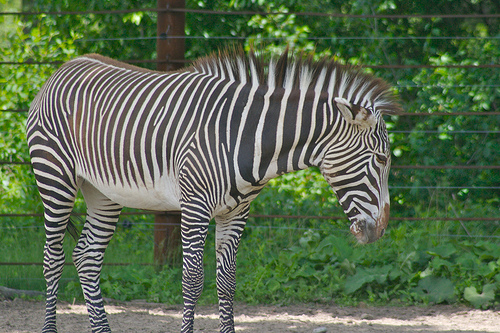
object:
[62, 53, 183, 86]
pole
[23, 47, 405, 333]
zebra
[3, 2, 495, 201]
trees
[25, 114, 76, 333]
leg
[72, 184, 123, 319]
leg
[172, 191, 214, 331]
leg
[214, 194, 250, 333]
leg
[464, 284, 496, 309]
green leaf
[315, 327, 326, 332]
rock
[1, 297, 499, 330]
dirt ground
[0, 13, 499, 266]
fence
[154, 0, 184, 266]
pole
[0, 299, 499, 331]
dirt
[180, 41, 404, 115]
zebra mane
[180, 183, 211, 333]
leg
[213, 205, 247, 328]
leg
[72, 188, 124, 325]
leg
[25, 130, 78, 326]
leg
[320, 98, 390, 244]
head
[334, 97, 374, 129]
ear